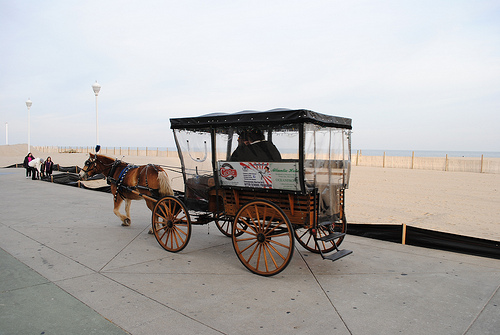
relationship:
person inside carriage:
[234, 130, 271, 161] [149, 106, 352, 276]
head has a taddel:
[78, 154, 101, 181] [94, 145, 102, 155]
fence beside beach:
[27, 143, 499, 177] [2, 143, 499, 243]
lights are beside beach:
[4, 80, 103, 166] [2, 143, 499, 243]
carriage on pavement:
[149, 105, 352, 276] [3, 166, 499, 334]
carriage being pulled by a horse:
[149, 105, 352, 276] [79, 154, 175, 235]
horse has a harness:
[79, 154, 175, 235] [106, 157, 143, 202]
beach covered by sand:
[2, 143, 499, 243] [4, 142, 499, 244]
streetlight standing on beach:
[91, 82, 101, 152] [2, 143, 499, 243]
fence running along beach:
[27, 143, 499, 177] [2, 143, 499, 243]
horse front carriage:
[77, 152, 172, 235] [149, 106, 352, 276]